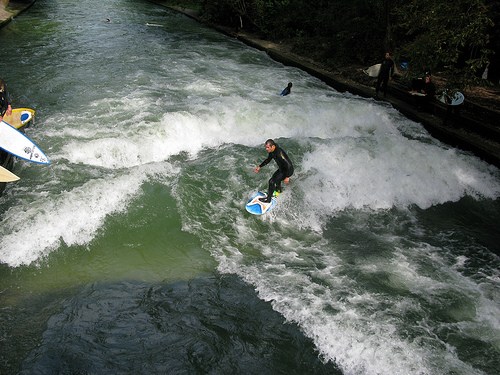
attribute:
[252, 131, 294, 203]
man — surfboarding, surfing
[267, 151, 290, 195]
wetsuit — wet, black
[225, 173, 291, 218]
surfboard — water, big, white, blue, ywllow, yellow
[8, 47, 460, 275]
water — zealous, wavy, boisterous, tumultuous, choppy, white, in distance, blue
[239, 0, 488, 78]
trees — tall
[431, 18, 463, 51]
leaves — green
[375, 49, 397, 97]
person — standing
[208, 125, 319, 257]
person — surfing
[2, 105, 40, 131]
boat — yellow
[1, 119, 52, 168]
surfboard — white